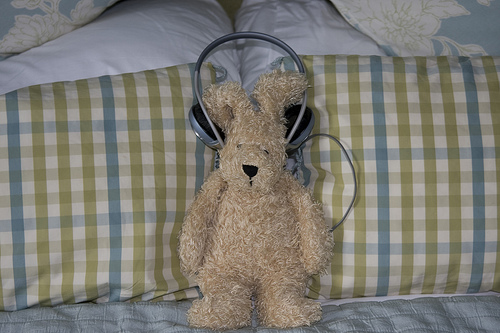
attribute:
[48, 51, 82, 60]
pillow case — white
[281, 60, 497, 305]
lines — long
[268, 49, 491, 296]
pillow — plaid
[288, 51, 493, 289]
lines — long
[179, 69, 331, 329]
rabbit — Stuffed, toy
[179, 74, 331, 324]
toy — Stuffed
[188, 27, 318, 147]
headphones — gray, black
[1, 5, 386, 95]
pillows — white